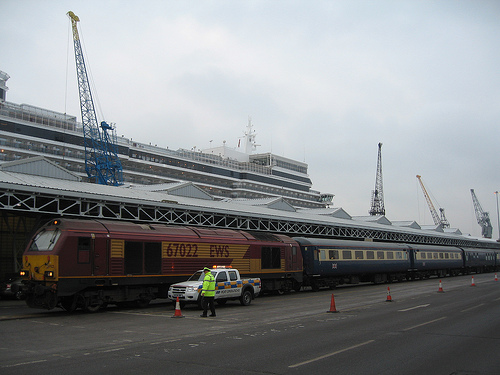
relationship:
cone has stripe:
[168, 291, 190, 316] [171, 300, 182, 310]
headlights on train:
[18, 269, 54, 278] [14, 213, 482, 310]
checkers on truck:
[211, 276, 261, 288] [165, 263, 263, 306]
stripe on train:
[314, 243, 463, 263] [19, 208, 481, 316]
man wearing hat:
[195, 265, 221, 318] [200, 264, 210, 274]